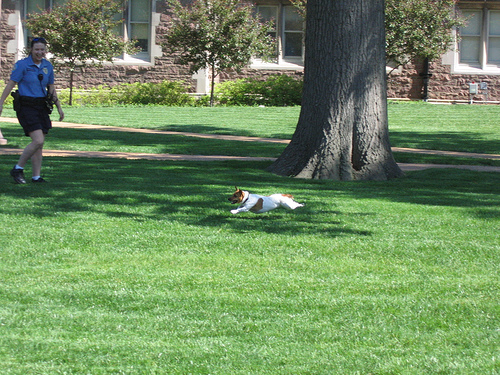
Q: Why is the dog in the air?
A: He jumped.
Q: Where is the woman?
A: To the left of the photo.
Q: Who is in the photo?
A: A woman.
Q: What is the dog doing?
A: Leaping.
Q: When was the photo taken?
A: Daytime.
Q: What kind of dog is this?
A: A terrier.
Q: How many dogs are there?
A: One.